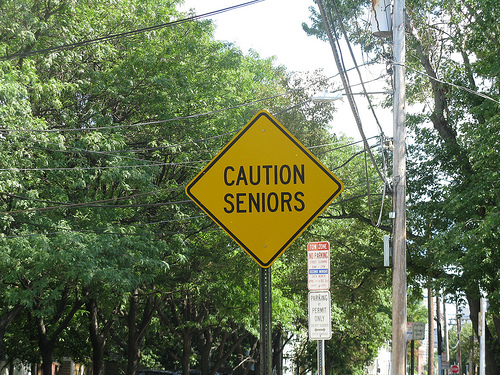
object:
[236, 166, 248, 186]
letter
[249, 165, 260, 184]
letter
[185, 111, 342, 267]
sign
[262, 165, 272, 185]
letter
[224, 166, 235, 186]
letter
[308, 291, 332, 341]
sign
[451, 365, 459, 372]
sign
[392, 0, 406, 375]
pole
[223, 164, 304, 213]
letting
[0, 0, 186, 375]
tree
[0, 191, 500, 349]
distance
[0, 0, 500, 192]
background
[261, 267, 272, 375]
pole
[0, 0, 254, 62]
wires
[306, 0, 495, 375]
trees